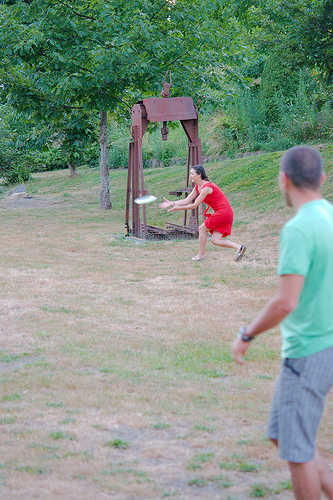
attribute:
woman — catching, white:
[176, 167, 233, 246]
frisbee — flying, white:
[136, 193, 159, 212]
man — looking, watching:
[263, 160, 333, 357]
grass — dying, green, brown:
[72, 262, 182, 372]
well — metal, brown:
[130, 78, 201, 141]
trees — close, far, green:
[181, 23, 294, 120]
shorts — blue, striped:
[287, 353, 320, 465]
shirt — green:
[288, 223, 328, 311]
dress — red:
[207, 190, 230, 221]